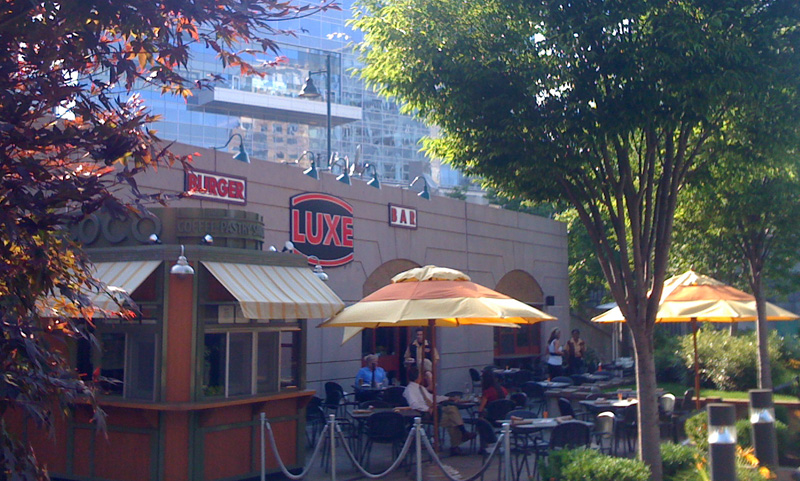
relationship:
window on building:
[380, 118, 398, 129] [0, 0, 644, 477]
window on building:
[288, 130, 298, 144] [0, 0, 644, 477]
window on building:
[138, 96, 149, 109] [0, 0, 644, 477]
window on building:
[381, 157, 398, 165] [0, 0, 644, 477]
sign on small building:
[176, 165, 248, 207] [0, 204, 348, 481]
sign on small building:
[380, 202, 422, 229] [0, 204, 348, 481]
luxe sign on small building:
[288, 191, 356, 270] [0, 204, 348, 481]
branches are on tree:
[560, 119, 714, 324] [353, 0, 782, 477]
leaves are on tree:
[8, 9, 210, 414] [1, 0, 347, 477]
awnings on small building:
[26, 227, 349, 320] [0, 200, 347, 477]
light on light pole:
[289, 52, 326, 98] [324, 53, 333, 172]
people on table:
[346, 356, 518, 404] [318, 395, 524, 429]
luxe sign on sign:
[271, 185, 368, 271] [387, 202, 419, 231]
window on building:
[242, 114, 272, 150] [237, 38, 427, 186]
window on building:
[266, 110, 292, 142] [237, 38, 427, 186]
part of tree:
[366, 21, 771, 197] [346, 13, 798, 219]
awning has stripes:
[199, 253, 345, 325] [197, 257, 349, 329]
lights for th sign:
[195, 124, 437, 197] [283, 191, 358, 269]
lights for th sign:
[195, 124, 437, 197] [176, 165, 248, 207]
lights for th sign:
[195, 124, 437, 197] [382, 203, 419, 233]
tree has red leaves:
[1, 0, 347, 477] [0, 5, 341, 417]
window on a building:
[201, 334, 230, 394] [0, 107, 577, 476]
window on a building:
[224, 326, 254, 403] [0, 107, 577, 476]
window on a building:
[261, 332, 281, 383] [0, 107, 577, 476]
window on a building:
[274, 331, 296, 387] [0, 107, 577, 476]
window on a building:
[117, 326, 157, 411] [0, 107, 577, 476]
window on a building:
[104, 328, 124, 394] [0, 107, 577, 476]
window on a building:
[286, 125, 296, 141] [0, 107, 577, 476]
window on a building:
[275, 129, 283, 141] [0, 107, 577, 476]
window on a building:
[355, 123, 372, 145] [0, 107, 577, 476]